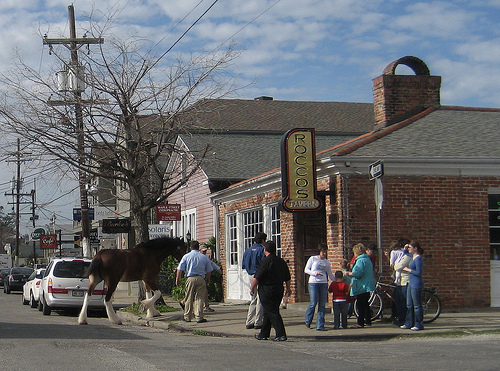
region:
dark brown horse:
[74, 217, 213, 338]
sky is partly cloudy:
[0, 3, 496, 112]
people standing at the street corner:
[173, 223, 480, 343]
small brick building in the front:
[203, 52, 499, 325]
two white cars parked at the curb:
[16, 250, 118, 326]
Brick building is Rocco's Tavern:
[270, 110, 338, 228]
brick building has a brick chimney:
[357, 46, 470, 157]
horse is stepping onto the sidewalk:
[77, 217, 205, 344]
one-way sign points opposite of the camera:
[352, 157, 387, 182]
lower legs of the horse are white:
[72, 233, 237, 337]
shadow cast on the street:
[18, 302, 103, 349]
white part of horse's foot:
[65, 288, 97, 331]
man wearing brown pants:
[177, 272, 219, 339]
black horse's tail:
[38, 253, 110, 293]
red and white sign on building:
[147, 200, 206, 222]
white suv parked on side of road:
[30, 249, 137, 305]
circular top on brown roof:
[364, 38, 444, 92]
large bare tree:
[33, 44, 213, 218]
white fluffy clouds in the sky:
[192, 21, 265, 66]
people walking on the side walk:
[164, 214, 441, 325]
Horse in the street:
[70, 225, 185, 323]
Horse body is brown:
[61, 232, 188, 333]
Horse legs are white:
[67, 281, 169, 335]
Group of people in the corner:
[170, 215, 434, 347]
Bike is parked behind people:
[347, 271, 445, 333]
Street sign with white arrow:
[357, 154, 392, 188]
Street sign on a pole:
[365, 178, 389, 212]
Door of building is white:
[214, 200, 289, 315]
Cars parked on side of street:
[1, 250, 113, 317]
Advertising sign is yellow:
[271, 117, 329, 221]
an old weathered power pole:
[35, 5, 130, 275]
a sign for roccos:
[266, 114, 336, 224]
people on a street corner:
[228, 227, 465, 349]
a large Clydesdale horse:
[45, 221, 199, 331]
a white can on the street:
[27, 252, 119, 316]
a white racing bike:
[346, 267, 457, 335]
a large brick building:
[196, 44, 498, 324]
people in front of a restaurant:
[30, 45, 499, 354]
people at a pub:
[137, 49, 497, 339]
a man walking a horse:
[47, 216, 229, 337]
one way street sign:
[365, 160, 386, 179]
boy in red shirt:
[328, 269, 350, 331]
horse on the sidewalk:
[85, 236, 187, 331]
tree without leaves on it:
[20, 69, 204, 236]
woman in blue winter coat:
[348, 242, 376, 329]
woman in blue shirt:
[402, 239, 426, 333]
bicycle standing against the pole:
[355, 264, 444, 329]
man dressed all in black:
[247, 237, 294, 346]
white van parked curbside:
[42, 253, 112, 315]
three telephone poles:
[2, 10, 97, 250]